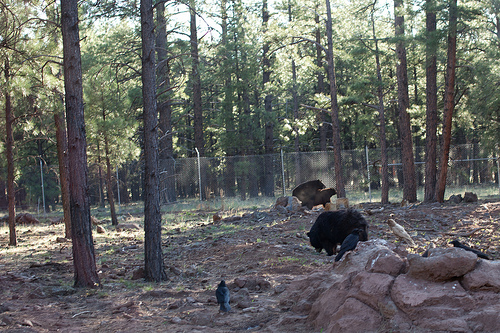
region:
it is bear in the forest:
[304, 201, 369, 254]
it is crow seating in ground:
[215, 275, 239, 322]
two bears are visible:
[283, 174, 339, 208]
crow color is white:
[212, 274, 238, 316]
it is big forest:
[7, 6, 498, 163]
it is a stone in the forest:
[352, 248, 477, 325]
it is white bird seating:
[382, 213, 419, 256]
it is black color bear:
[297, 206, 369, 257]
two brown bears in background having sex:
[290, 178, 335, 208]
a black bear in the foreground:
[302, 210, 366, 250]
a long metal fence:
[2, 143, 498, 206]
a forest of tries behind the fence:
[7, 43, 498, 190]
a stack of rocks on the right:
[332, 243, 499, 331]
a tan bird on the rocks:
[386, 219, 415, 248]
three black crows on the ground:
[217, 230, 489, 312]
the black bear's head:
[307, 229, 321, 251]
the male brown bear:
[291, 178, 323, 203]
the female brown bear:
[308, 188, 335, 206]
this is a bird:
[185, 262, 250, 315]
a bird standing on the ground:
[185, 262, 287, 331]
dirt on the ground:
[110, 265, 290, 331]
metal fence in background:
[50, 136, 493, 223]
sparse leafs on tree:
[28, 16, 128, 187]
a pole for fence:
[188, 142, 217, 212]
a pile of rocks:
[306, 219, 494, 331]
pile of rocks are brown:
[312, 232, 490, 330]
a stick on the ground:
[395, 207, 479, 242]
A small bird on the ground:
[205, 278, 245, 311]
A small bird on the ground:
[330, 226, 367, 259]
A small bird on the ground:
[380, 205, 418, 249]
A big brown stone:
[304, 246, 472, 324]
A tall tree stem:
[27, 10, 104, 265]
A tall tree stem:
[130, 43, 182, 285]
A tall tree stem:
[380, 69, 420, 181]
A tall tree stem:
[413, 50, 434, 177]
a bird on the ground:
[211, 275, 237, 320]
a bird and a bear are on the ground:
[306, 208, 378, 270]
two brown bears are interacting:
[290, 175, 342, 217]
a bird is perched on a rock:
[383, 213, 424, 265]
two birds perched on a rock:
[331, 216, 426, 273]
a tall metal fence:
[0, 136, 497, 224]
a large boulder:
[317, 251, 499, 331]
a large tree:
[128, 0, 171, 281]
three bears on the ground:
[286, 175, 373, 258]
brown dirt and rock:
[6, 301, 310, 331]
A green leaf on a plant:
[84, 54, 89, 56]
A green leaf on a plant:
[100, 40, 107, 43]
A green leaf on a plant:
[274, 28, 276, 29]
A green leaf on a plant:
[344, 16, 346, 18]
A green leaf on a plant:
[428, 29, 431, 33]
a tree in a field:
[5, 17, 18, 248]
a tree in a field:
[23, 1, 108, 279]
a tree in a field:
[150, 2, 191, 204]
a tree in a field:
[171, 1, 214, 201]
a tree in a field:
[246, 5, 278, 196]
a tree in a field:
[318, 5, 353, 197]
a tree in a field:
[340, 8, 428, 202]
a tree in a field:
[406, 0, 447, 203]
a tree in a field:
[366, 1, 497, 206]